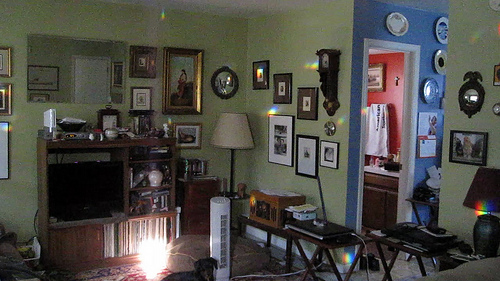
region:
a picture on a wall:
[128, 41, 156, 76]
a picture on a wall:
[160, 42, 205, 114]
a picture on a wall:
[250, 56, 270, 90]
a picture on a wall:
[269, 67, 294, 105]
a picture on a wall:
[293, 80, 321, 118]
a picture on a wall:
[263, 110, 293, 169]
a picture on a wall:
[295, 131, 317, 178]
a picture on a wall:
[316, 133, 340, 171]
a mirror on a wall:
[212, 64, 239, 96]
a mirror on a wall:
[28, 34, 122, 109]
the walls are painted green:
[18, 21, 344, 251]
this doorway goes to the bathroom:
[358, 10, 443, 229]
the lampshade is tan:
[199, 99, 259, 224]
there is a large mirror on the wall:
[16, 6, 241, 176]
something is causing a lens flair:
[31, 75, 194, 280]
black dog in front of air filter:
[144, 180, 244, 278]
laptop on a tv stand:
[263, 188, 381, 273]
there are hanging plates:
[367, 5, 458, 150]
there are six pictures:
[246, 31, 350, 198]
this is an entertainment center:
[26, 70, 202, 277]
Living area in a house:
[2, 5, 498, 279]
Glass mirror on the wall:
[22, 30, 128, 107]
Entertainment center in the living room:
[36, 123, 180, 279]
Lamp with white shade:
[211, 109, 256, 241]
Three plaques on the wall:
[250, 57, 320, 126]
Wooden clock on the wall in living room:
[312, 45, 344, 119]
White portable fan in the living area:
[207, 193, 232, 279]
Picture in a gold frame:
[160, 44, 207, 117]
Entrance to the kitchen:
[365, 46, 407, 235]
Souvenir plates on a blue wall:
[385, 10, 450, 47]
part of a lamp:
[231, 124, 244, 138]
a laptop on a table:
[319, 227, 325, 231]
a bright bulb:
[136, 237, 172, 260]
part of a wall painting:
[300, 95, 310, 115]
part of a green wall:
[264, 15, 272, 32]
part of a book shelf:
[127, 220, 139, 227]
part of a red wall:
[390, 65, 397, 75]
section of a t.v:
[91, 172, 102, 183]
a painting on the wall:
[181, 64, 196, 100]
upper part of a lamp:
[228, 124, 240, 141]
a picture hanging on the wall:
[249, 60, 269, 87]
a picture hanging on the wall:
[132, 87, 152, 109]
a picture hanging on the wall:
[133, 47, 158, 75]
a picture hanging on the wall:
[161, 42, 203, 115]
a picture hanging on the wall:
[271, 72, 292, 104]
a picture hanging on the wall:
[294, 84, 319, 121]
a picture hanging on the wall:
[266, 112, 294, 166]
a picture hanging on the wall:
[294, 130, 319, 179]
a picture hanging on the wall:
[319, 137, 339, 169]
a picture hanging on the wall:
[172, 117, 204, 150]